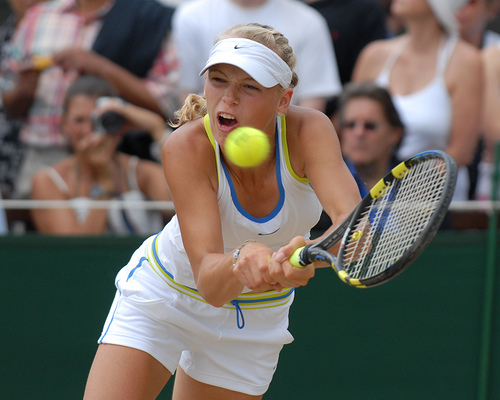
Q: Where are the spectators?
A: In the stadium seats.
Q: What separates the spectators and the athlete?
A: A green fence.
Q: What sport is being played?
A: Tennis.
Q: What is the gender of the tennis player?
A: Female.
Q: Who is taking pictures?
A: A woman spectator.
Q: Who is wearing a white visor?
A: Tennis player.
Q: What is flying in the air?
A: Tennis ball.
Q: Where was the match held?
A: Tennis court.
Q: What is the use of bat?
A: Hit the ball.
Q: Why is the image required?
A: Remembrance.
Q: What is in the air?
A: Ball.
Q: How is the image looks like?
A: Good.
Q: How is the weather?
A: Good.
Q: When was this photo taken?
A: During a tennis match.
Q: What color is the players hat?
A: White.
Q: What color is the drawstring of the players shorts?
A: Blue.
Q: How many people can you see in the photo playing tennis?
A: One.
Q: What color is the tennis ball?
A: Yellow.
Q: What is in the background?
A: People.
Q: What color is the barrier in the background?
A: Green.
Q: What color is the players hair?
A: Blonde.